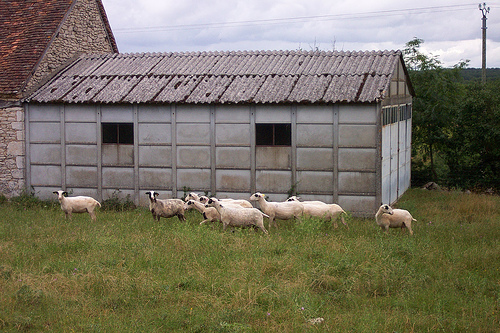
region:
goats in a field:
[48, 188, 419, 238]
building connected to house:
[28, 48, 414, 221]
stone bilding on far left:
[0, 2, 119, 200]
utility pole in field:
[478, 3, 493, 68]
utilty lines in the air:
[111, 1, 498, 35]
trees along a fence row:
[406, 35, 497, 186]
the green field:
[5, 190, 497, 330]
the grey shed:
[0, 0, 413, 215]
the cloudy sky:
[103, 0, 499, 66]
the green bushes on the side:
[402, 49, 499, 188]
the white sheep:
[54, 184, 419, 235]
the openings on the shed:
[96, 115, 292, 150]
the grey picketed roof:
[31, 48, 399, 102]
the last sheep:
[368, 201, 420, 236]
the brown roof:
[1, 0, 93, 110]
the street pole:
[481, 3, 489, 70]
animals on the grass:
[6, 152, 423, 269]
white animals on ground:
[67, 131, 422, 300]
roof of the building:
[37, 33, 404, 123]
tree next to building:
[408, 80, 474, 152]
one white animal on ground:
[360, 190, 420, 231]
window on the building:
[232, 85, 312, 185]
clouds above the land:
[216, 5, 371, 38]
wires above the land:
[233, 7, 320, 39]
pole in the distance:
[453, 10, 495, 76]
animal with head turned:
[331, 183, 442, 261]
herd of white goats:
[65, 171, 419, 273]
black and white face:
[132, 181, 164, 205]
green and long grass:
[186, 224, 281, 313]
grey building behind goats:
[56, 107, 390, 187]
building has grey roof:
[54, 36, 386, 111]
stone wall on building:
[37, 9, 94, 104]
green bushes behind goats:
[415, 84, 470, 191]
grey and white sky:
[308, 9, 393, 64]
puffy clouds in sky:
[185, 12, 320, 49]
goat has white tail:
[407, 196, 421, 229]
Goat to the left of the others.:
[53, 190, 102, 221]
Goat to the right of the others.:
[375, 202, 418, 234]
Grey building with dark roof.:
[16, 49, 413, 214]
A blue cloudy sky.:
[103, 0, 498, 65]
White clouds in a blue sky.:
[104, 2, 498, 60]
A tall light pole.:
[478, 2, 490, 68]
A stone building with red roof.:
[0, 2, 118, 201]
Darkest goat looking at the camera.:
[145, 190, 185, 222]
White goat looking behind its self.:
[374, 204, 418, 234]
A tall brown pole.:
[480, 16, 488, 85]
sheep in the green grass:
[53, 181, 426, 240]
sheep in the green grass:
[140, 186, 187, 223]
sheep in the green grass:
[370, 193, 425, 235]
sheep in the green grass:
[241, 191, 343, 219]